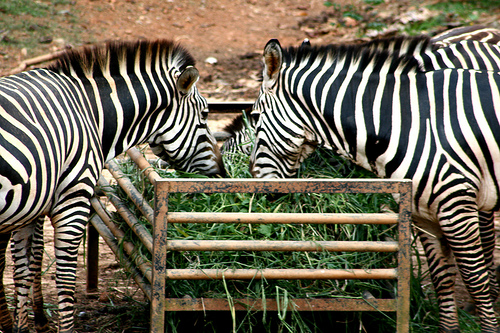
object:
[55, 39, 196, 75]
maine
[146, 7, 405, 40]
gravel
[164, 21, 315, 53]
ground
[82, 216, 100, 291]
legs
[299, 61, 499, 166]
stripes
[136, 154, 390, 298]
grass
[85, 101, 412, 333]
crate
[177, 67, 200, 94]
ear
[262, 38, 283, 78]
ear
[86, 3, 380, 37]
dirt ground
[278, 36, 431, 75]
mane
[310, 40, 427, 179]
neck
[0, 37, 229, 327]
zebra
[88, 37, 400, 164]
two zebra's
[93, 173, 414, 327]
fence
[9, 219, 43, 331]
leg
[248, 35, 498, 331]
zebra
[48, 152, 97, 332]
leg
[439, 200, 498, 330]
leg